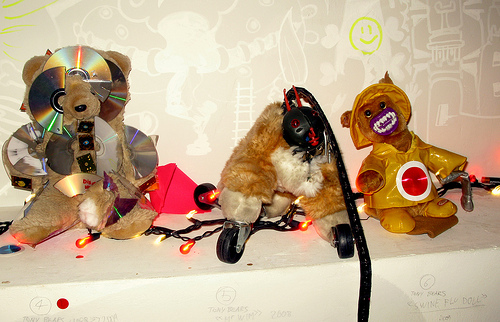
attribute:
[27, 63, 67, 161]
dvds — sliced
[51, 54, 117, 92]
cd — broken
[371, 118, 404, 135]
lips — purple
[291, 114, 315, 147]
mask — black, red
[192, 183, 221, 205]
light bulb — orange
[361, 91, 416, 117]
hat — yellow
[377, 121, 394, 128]
teeth — sharp, white, purple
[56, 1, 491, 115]
wallpaper — white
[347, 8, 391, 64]
happy face — yellow, smiley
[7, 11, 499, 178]
wall — white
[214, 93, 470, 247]
animals — small, plush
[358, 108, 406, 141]
face — yellow, grinning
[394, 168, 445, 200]
target — red, white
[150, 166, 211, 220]
paper — red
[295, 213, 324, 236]
light — orange, red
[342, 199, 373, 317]
rope — thick, black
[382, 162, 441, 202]
design — round, white, shiny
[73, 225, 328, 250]
lights — red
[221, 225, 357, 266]
wheels — black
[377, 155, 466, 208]
raincoat — yellow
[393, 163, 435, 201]
circle — red, white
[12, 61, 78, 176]
cds — broken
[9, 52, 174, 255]
teddy bear — sitting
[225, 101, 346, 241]
plushie — white, orange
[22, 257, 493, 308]
shelf — white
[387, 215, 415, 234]
rain shoe — yellow, plastic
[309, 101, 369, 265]
tubing — long, black